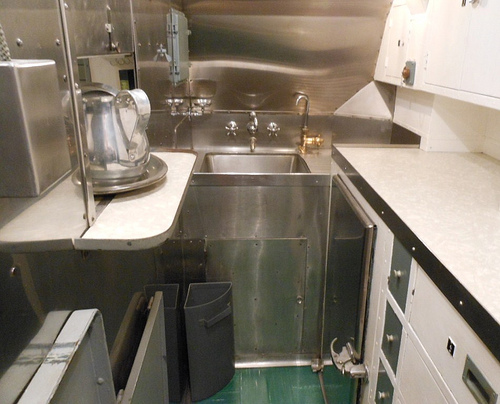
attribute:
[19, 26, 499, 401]
kitchen —  area,  nasty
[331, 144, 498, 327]
counter — empty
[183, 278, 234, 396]
corner bin —   for trash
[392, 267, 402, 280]
drawer pull — stainless steel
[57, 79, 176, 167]
kettle —  silver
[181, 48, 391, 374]
kitchen area —  nasty,   area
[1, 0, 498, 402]
kitchen area —  nasty,  area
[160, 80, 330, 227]
sink —  silver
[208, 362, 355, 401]
floor — dark green, linoleum